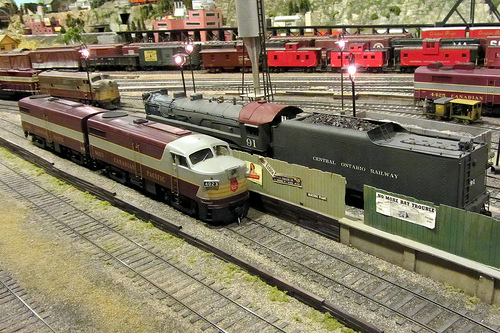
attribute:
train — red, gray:
[4, 104, 493, 330]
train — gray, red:
[139, 87, 489, 217]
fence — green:
[221, 142, 496, 262]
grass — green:
[9, 144, 354, 330]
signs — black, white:
[251, 158, 331, 207]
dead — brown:
[15, 186, 193, 330]